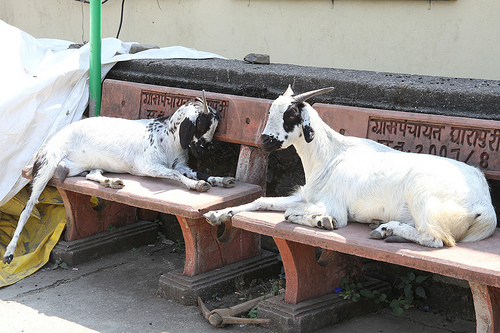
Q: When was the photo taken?
A: During the day.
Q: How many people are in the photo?
A: None.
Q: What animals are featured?
A: Goats.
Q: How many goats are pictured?
A: Two.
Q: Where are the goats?
A: On benches.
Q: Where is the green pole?
A: Next to the bench on the left.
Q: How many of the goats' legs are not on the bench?
A: One.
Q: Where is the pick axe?
A: On the grond between the two benches.